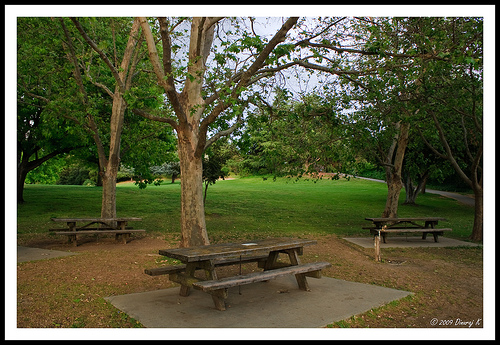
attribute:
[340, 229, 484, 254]
slab — concrete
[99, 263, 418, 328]
slab — concrete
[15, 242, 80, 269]
slab — concrete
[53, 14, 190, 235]
tree — large, hard, wood, green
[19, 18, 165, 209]
tree — large, hard, wood, green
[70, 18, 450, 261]
tree — large, hard, wood, green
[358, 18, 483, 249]
tree — large, hard, wood, green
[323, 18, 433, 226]
tree — large, hard, wood, green